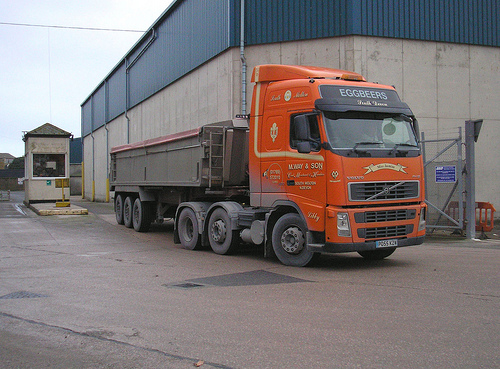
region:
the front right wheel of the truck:
[269, 199, 322, 274]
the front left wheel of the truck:
[356, 241, 402, 265]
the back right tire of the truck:
[110, 189, 126, 226]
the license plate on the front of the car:
[370, 234, 404, 251]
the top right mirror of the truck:
[289, 106, 314, 141]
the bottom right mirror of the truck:
[289, 139, 319, 156]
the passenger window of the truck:
[287, 109, 328, 160]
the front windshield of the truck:
[320, 104, 427, 158]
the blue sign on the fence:
[430, 161, 462, 188]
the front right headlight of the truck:
[334, 211, 353, 241]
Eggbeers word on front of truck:
[327, 83, 391, 100]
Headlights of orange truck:
[323, 200, 435, 244]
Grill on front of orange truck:
[343, 175, 425, 250]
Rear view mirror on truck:
[289, 109, 319, 161]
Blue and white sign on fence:
[430, 157, 460, 189]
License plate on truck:
[368, 233, 400, 253]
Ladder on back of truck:
[200, 123, 232, 199]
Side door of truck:
[272, 102, 334, 213]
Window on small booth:
[24, 143, 75, 186]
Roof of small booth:
[21, 116, 80, 151]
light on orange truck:
[336, 211, 351, 237]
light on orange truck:
[415, 213, 425, 238]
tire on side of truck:
[275, 220, 307, 268]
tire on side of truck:
[208, 213, 230, 254]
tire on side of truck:
[178, 215, 200, 250]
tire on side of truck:
[132, 207, 144, 232]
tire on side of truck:
[123, 198, 133, 225]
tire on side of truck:
[114, 196, 125, 223]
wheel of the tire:
[278, 223, 302, 248]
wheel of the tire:
[213, 220, 227, 238]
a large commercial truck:
[106, 60, 428, 271]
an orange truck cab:
[247, 57, 431, 267]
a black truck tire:
[270, 210, 312, 266]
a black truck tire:
[203, 207, 238, 254]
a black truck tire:
[174, 206, 201, 249]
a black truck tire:
[129, 195, 148, 231]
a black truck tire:
[122, 193, 133, 226]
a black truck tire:
[112, 192, 123, 222]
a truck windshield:
[323, 108, 420, 155]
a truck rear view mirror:
[291, 112, 318, 150]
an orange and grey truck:
[107, 63, 429, 263]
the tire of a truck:
[203, 205, 233, 255]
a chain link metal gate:
[417, 127, 465, 234]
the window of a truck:
[320, 105, 417, 154]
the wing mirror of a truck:
[291, 113, 323, 155]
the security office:
[19, 123, 75, 205]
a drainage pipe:
[99, 80, 115, 199]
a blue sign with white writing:
[434, 163, 456, 183]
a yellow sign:
[52, 177, 72, 207]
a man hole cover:
[168, 278, 205, 291]